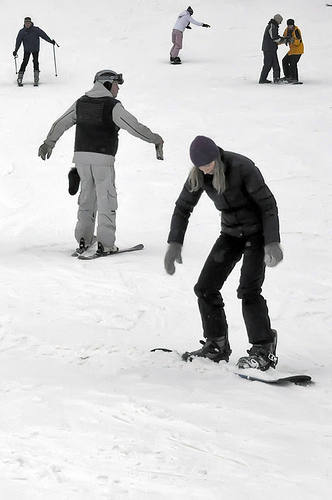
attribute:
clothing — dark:
[163, 146, 282, 343]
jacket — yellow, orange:
[279, 25, 304, 57]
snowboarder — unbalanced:
[167, 4, 210, 65]